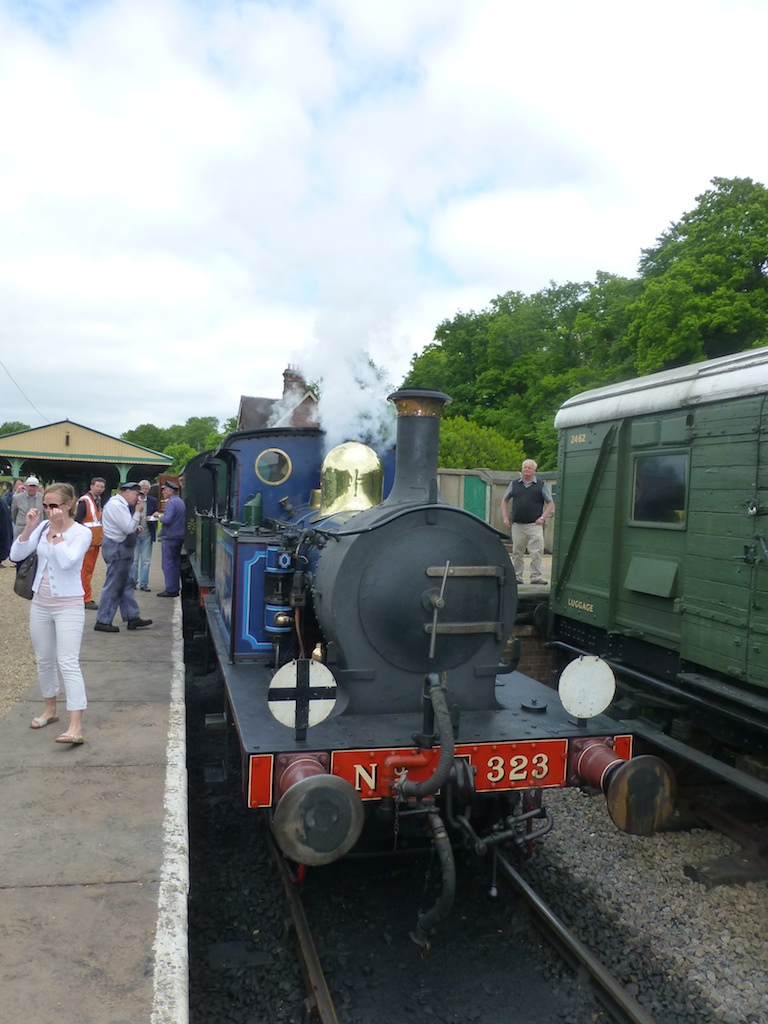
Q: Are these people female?
A: No, they are both male and female.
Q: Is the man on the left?
A: Yes, the man is on the left of the image.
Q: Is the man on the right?
A: No, the man is on the left of the image.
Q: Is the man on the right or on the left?
A: The man is on the left of the image.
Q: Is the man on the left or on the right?
A: The man is on the left of the image.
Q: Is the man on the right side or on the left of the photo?
A: The man is on the left of the image.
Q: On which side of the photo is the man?
A: The man is on the left of the image.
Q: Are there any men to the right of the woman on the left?
A: Yes, there is a man to the right of the woman.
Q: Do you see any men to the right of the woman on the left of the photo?
A: Yes, there is a man to the right of the woman.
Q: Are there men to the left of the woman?
A: No, the man is to the right of the woman.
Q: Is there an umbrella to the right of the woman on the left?
A: No, there is a man to the right of the woman.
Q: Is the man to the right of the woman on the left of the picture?
A: Yes, the man is to the right of the woman.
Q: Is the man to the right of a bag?
A: No, the man is to the right of the woman.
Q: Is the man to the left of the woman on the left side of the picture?
A: No, the man is to the right of the woman.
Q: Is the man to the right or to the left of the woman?
A: The man is to the right of the woman.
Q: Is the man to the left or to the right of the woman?
A: The man is to the right of the woman.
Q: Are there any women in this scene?
A: Yes, there is a woman.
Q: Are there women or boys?
A: Yes, there is a woman.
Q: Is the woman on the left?
A: Yes, the woman is on the left of the image.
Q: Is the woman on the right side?
A: No, the woman is on the left of the image.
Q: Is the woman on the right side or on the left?
A: The woman is on the left of the image.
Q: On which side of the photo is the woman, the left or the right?
A: The woman is on the left of the image.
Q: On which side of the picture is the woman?
A: The woman is on the left of the image.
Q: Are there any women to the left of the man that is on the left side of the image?
A: Yes, there is a woman to the left of the man.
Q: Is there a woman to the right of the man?
A: No, the woman is to the left of the man.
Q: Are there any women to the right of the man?
A: No, the woman is to the left of the man.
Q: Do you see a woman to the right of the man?
A: No, the woman is to the left of the man.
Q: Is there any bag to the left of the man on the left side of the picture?
A: No, there is a woman to the left of the man.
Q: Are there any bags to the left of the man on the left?
A: No, there is a woman to the left of the man.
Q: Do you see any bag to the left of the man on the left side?
A: No, there is a woman to the left of the man.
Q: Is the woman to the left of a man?
A: Yes, the woman is to the left of a man.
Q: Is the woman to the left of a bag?
A: No, the woman is to the left of a man.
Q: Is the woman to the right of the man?
A: No, the woman is to the left of the man.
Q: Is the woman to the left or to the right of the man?
A: The woman is to the left of the man.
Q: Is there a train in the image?
A: Yes, there is a train.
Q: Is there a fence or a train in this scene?
A: Yes, there is a train.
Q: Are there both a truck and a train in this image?
A: No, there is a train but no trucks.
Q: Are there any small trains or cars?
A: Yes, there is a small train.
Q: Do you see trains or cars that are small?
A: Yes, the train is small.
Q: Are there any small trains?
A: Yes, there is a small train.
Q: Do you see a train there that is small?
A: Yes, there is a train that is small.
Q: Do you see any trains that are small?
A: Yes, there is a train that is small.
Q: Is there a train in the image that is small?
A: Yes, there is a train that is small.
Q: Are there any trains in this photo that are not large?
A: Yes, there is a small train.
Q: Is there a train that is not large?
A: Yes, there is a small train.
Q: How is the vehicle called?
A: The vehicle is a train.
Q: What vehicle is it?
A: The vehicle is a train.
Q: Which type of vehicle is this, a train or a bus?
A: That is a train.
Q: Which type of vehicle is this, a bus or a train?
A: That is a train.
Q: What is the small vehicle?
A: The vehicle is a train.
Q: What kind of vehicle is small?
A: The vehicle is a train.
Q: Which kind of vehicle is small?
A: The vehicle is a train.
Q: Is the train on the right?
A: Yes, the train is on the right of the image.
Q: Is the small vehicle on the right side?
A: Yes, the train is on the right of the image.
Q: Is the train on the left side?
A: No, the train is on the right of the image.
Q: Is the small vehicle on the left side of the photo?
A: No, the train is on the right of the image.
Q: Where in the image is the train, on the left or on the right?
A: The train is on the right of the image.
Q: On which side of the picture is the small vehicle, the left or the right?
A: The train is on the right of the image.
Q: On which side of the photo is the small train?
A: The train is on the right of the image.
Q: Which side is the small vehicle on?
A: The train is on the right of the image.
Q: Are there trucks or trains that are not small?
A: No, there is a train but it is small.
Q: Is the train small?
A: Yes, the train is small.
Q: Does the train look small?
A: Yes, the train is small.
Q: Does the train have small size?
A: Yes, the train is small.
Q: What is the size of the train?
A: The train is small.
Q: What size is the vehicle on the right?
A: The train is small.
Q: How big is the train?
A: The train is small.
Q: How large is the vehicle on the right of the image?
A: The train is small.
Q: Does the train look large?
A: No, the train is small.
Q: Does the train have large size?
A: No, the train is small.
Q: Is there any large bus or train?
A: No, there is a train but it is small.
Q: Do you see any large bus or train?
A: No, there is a train but it is small.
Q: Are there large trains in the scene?
A: No, there is a train but it is small.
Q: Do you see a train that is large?
A: No, there is a train but it is small.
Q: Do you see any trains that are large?
A: No, there is a train but it is small.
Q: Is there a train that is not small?
A: No, there is a train but it is small.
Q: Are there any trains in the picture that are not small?
A: No, there is a train but it is small.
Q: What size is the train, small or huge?
A: The train is small.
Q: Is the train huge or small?
A: The train is small.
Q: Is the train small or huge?
A: The train is small.